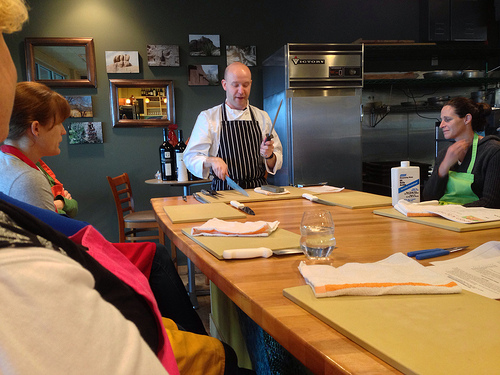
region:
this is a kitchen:
[85, 73, 420, 281]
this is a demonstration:
[90, 48, 470, 370]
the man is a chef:
[182, 28, 333, 230]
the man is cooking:
[192, 45, 314, 245]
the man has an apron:
[205, 90, 296, 205]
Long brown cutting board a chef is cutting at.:
[197, 186, 316, 204]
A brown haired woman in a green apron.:
[420, 99, 498, 208]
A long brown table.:
[149, 184, 499, 373]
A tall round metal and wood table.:
[144, 176, 214, 309]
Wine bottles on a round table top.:
[158, 127, 188, 183]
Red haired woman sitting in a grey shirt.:
[0, 80, 207, 336]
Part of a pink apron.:
[66, 224, 178, 374]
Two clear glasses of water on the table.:
[298, 208, 338, 261]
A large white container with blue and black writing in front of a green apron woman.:
[390, 160, 421, 203]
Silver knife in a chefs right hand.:
[223, 173, 248, 199]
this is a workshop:
[172, 52, 378, 304]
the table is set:
[230, 192, 356, 292]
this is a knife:
[200, 209, 292, 276]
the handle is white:
[219, 243, 296, 290]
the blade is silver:
[279, 237, 309, 256]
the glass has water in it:
[300, 214, 347, 265]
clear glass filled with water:
[295, 225, 339, 263]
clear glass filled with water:
[295, 205, 335, 238]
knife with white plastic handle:
[220, 239, 307, 265]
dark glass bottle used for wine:
[154, 123, 178, 180]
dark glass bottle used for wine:
[173, 125, 188, 180]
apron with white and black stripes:
[207, 100, 264, 190]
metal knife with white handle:
[228, 195, 255, 217]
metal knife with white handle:
[300, 188, 338, 208]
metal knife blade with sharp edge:
[221, 170, 251, 200]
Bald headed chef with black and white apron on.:
[181, 61, 282, 189]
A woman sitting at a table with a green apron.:
[421, 97, 498, 207]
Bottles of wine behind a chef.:
[158, 126, 187, 182]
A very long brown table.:
[150, 182, 498, 372]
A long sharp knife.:
[222, 174, 247, 199]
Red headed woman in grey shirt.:
[0, 79, 207, 336]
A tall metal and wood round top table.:
[144, 176, 211, 309]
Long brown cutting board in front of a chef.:
[195, 185, 312, 208]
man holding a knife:
[174, 44, 294, 199]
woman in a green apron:
[410, 91, 498, 203]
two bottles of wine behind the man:
[151, 114, 200, 190]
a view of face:
[211, 53, 291, 128]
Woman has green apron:
[421, 93, 499, 206]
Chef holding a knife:
[180, 57, 285, 198]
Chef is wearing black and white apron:
[181, 60, 284, 191]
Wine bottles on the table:
[142, 122, 225, 312]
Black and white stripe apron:
[208, 98, 269, 191]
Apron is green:
[435, 132, 483, 207]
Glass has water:
[299, 206, 336, 262]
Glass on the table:
[146, 183, 499, 374]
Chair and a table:
[102, 168, 217, 311]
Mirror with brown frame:
[21, 35, 98, 91]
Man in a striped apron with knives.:
[180, 63, 280, 188]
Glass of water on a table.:
[300, 208, 342, 266]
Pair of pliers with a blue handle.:
[408, 241, 473, 257]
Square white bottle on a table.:
[391, 159, 421, 206]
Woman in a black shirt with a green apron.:
[426, 99, 496, 205]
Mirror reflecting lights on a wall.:
[103, 75, 180, 127]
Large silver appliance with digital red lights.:
[261, 40, 366, 189]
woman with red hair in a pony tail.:
[1, 82, 71, 214]